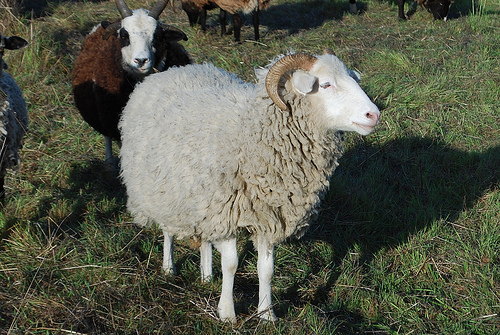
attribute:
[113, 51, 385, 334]
sheep — white, dirty, wooly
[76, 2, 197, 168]
sheep — brown, fluffy, black, white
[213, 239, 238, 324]
leg — white, sticking out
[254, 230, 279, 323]
leg — white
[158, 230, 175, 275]
leg — rear, back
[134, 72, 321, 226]
fur — dirty, white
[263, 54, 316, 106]
horn — single, curved, brown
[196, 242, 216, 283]
leg — back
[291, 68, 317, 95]
ear — white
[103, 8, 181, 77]
head — white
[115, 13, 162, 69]
face — white